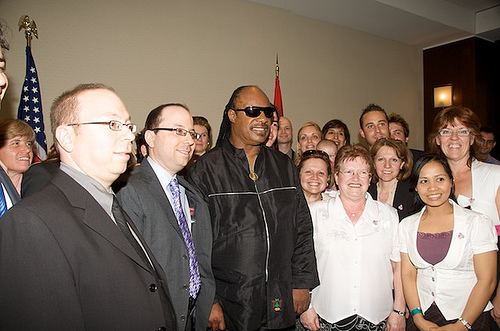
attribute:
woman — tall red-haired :
[418, 100, 489, 151]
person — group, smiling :
[186, 82, 323, 329]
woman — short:
[292, 144, 409, 329]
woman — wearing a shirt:
[319, 141, 406, 326]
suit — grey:
[5, 175, 174, 329]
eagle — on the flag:
[15, 13, 46, 37]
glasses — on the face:
[242, 104, 291, 125]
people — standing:
[340, 151, 482, 296]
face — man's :
[235, 88, 269, 145]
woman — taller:
[424, 102, 499, 227]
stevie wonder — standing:
[182, 54, 319, 329]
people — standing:
[0, 34, 496, 329]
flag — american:
[8, 22, 54, 154]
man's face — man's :
[41, 110, 159, 133]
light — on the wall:
[419, 76, 461, 113]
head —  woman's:
[302, 149, 331, 194]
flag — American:
[9, 14, 67, 161]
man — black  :
[190, 85, 320, 328]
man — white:
[115, 100, 228, 330]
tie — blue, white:
[167, 175, 203, 300]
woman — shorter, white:
[291, 146, 338, 203]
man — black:
[167, 71, 331, 329]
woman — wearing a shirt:
[394, 147, 499, 322]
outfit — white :
[393, 202, 494, 313]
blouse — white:
[306, 192, 403, 325]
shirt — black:
[188, 142, 317, 321]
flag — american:
[13, 46, 46, 142]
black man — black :
[198, 84, 319, 329]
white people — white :
[2, 37, 214, 327]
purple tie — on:
[155, 167, 207, 300]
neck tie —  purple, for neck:
[167, 177, 202, 299]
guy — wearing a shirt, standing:
[2, 82, 179, 328]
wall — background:
[56, 22, 495, 159]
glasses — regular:
[59, 108, 153, 140]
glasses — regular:
[138, 110, 207, 145]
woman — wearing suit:
[367, 140, 418, 214]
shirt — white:
[312, 200, 402, 320]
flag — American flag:
[16, 44, 46, 166]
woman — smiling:
[0, 116, 35, 215]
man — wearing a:
[130, 99, 220, 324]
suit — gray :
[115, 160, 215, 329]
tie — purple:
[166, 173, 210, 306]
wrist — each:
[388, 304, 408, 316]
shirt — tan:
[378, 184, 395, 205]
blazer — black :
[369, 177, 419, 218]